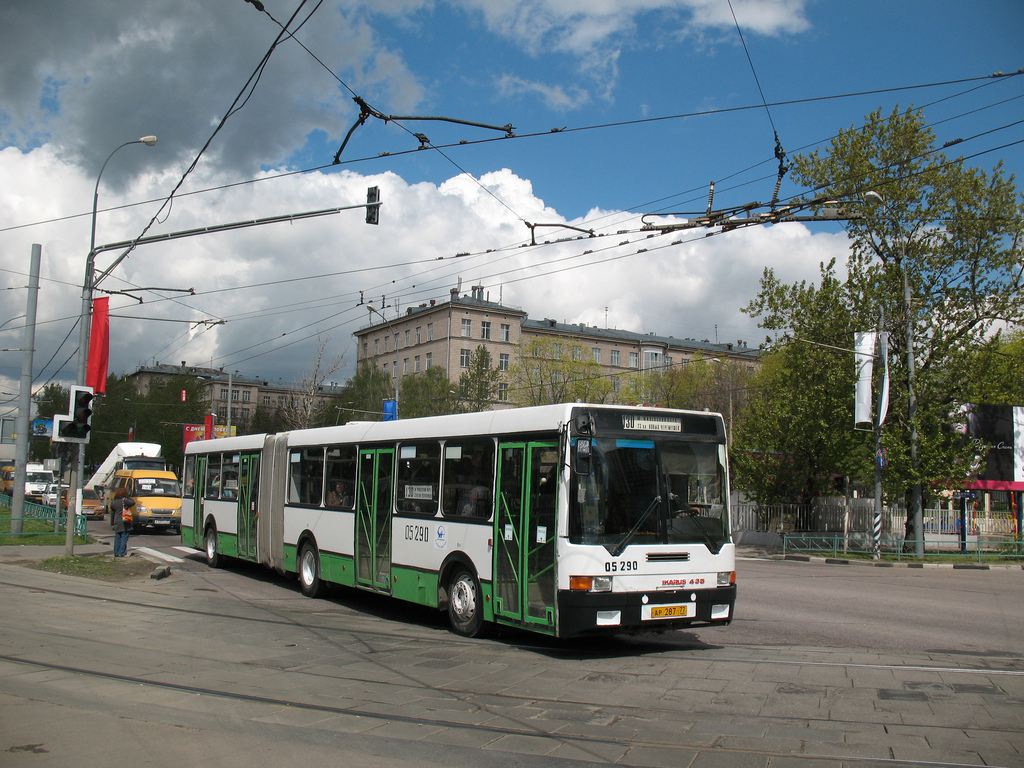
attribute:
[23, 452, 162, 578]
car — orange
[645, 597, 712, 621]
license plate — yellow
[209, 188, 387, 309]
clouds — white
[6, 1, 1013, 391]
sky — blue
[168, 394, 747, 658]
green/white bus — long